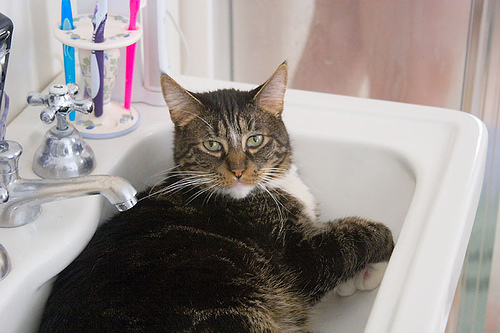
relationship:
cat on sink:
[35, 59, 394, 331] [0, 31, 498, 331]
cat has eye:
[35, 59, 394, 331] [243, 130, 265, 149]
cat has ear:
[35, 59, 394, 331] [145, 69, 260, 146]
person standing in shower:
[288, 2, 470, 104] [208, 1, 488, 114]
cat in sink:
[35, 59, 394, 331] [0, 31, 498, 331]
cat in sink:
[35, 59, 394, 331] [16, 80, 486, 331]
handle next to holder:
[27, 73, 104, 134] [54, 9, 145, 125]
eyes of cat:
[195, 127, 278, 158] [108, 53, 430, 305]